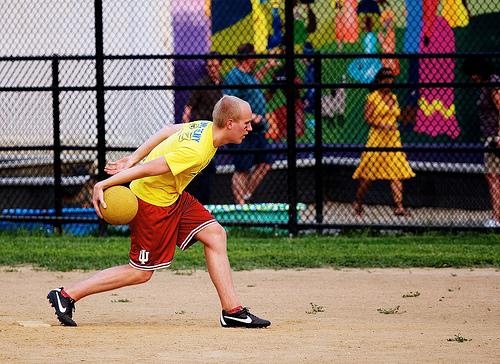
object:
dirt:
[0, 265, 500, 363]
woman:
[350, 65, 418, 217]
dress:
[350, 91, 416, 183]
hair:
[211, 95, 242, 128]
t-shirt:
[128, 119, 218, 208]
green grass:
[1, 227, 499, 273]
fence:
[0, 0, 498, 240]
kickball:
[95, 185, 138, 225]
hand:
[90, 184, 109, 219]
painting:
[171, 0, 469, 144]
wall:
[11, 2, 497, 210]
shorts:
[122, 181, 219, 272]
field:
[0, 231, 500, 363]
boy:
[45, 94, 275, 329]